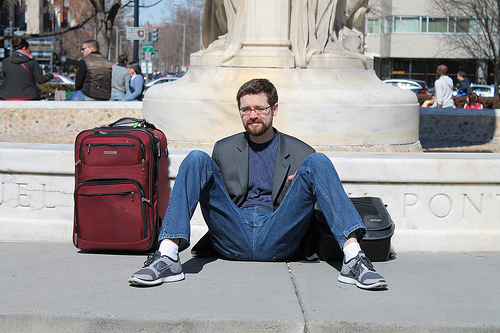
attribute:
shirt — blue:
[122, 71, 146, 102]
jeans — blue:
[153, 148, 368, 253]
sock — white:
[339, 231, 362, 264]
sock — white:
[152, 240, 181, 260]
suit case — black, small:
[313, 193, 397, 259]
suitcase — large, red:
[72, 114, 172, 250]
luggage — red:
[72, 117, 172, 257]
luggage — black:
[314, 194, 393, 258]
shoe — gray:
[336, 248, 386, 288]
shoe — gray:
[127, 251, 184, 285]